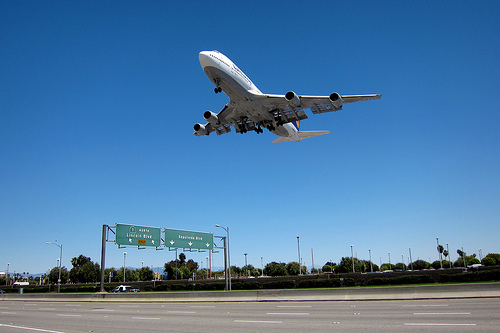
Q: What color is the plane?
A: White.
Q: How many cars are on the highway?
A: Zero.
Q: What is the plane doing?
A: Taking off.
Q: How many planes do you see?
A: One.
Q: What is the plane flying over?
A: A highway.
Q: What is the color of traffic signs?
A: Green.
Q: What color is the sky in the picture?
A: Blue.